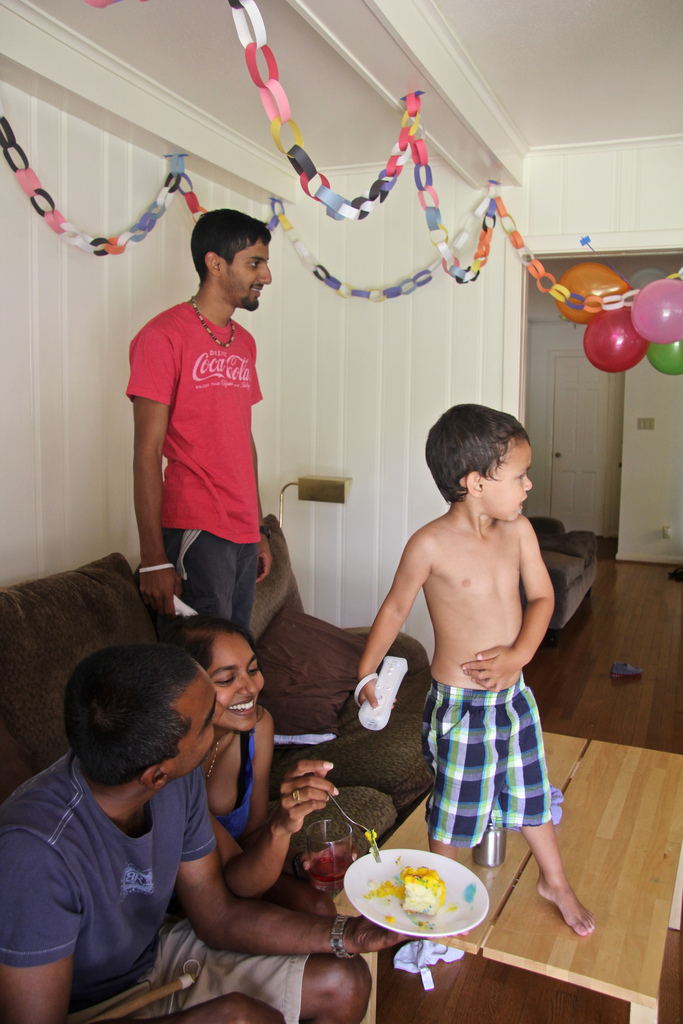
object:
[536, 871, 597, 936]
foot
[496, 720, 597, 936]
leg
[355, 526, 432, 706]
arm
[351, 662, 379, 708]
hand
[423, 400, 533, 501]
hair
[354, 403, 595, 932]
person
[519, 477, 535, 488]
nose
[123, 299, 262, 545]
shirt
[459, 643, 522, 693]
hand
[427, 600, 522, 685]
belly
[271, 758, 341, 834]
hand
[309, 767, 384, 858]
fork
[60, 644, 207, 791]
hair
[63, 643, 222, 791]
head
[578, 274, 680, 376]
balloons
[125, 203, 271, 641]
man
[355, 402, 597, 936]
boy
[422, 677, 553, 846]
shorts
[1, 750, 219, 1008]
t-shirt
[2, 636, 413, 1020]
man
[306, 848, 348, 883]
liquid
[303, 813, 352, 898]
glass